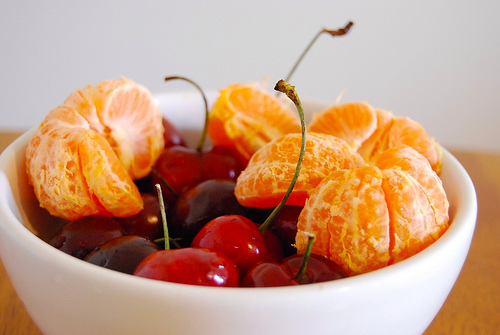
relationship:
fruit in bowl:
[24, 75, 452, 287] [0, 76, 474, 333]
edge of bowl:
[117, 258, 362, 328] [0, 76, 474, 333]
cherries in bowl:
[61, 115, 345, 318] [0, 76, 474, 333]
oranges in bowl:
[221, 74, 456, 286] [0, 76, 474, 333]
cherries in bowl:
[83, 135, 363, 303] [0, 76, 474, 333]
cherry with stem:
[202, 75, 312, 265] [256, 72, 309, 232]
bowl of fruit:
[0, 76, 474, 333] [21, 77, 448, 281]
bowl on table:
[0, 76, 474, 333] [2, 121, 498, 333]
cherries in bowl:
[58, 107, 345, 292] [0, 76, 474, 333]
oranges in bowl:
[293, 144, 451, 276] [6, 92, 446, 323]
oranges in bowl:
[47, 99, 166, 220] [29, 85, 411, 327]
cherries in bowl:
[143, 150, 301, 300] [29, 85, 411, 327]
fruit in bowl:
[24, 75, 452, 287] [56, 200, 445, 319]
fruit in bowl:
[24, 75, 452, 287] [0, 90, 479, 332]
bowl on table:
[0, 90, 479, 332] [431, 234, 499, 304]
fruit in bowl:
[92, 115, 357, 261] [54, 237, 470, 332]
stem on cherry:
[245, 101, 325, 196] [159, 210, 303, 298]